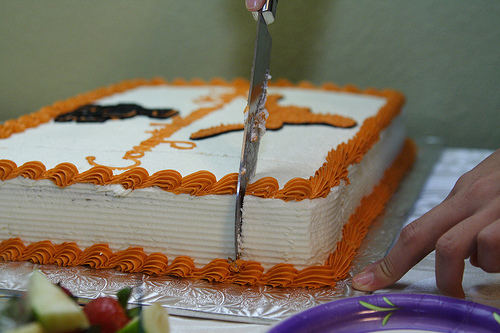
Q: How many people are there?
A: One.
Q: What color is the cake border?
A: Orange.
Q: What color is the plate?
A: Purple.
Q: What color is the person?
A: White.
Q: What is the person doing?
A: Cutting the cake.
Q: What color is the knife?
A: Silver.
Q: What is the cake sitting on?
A: Table.